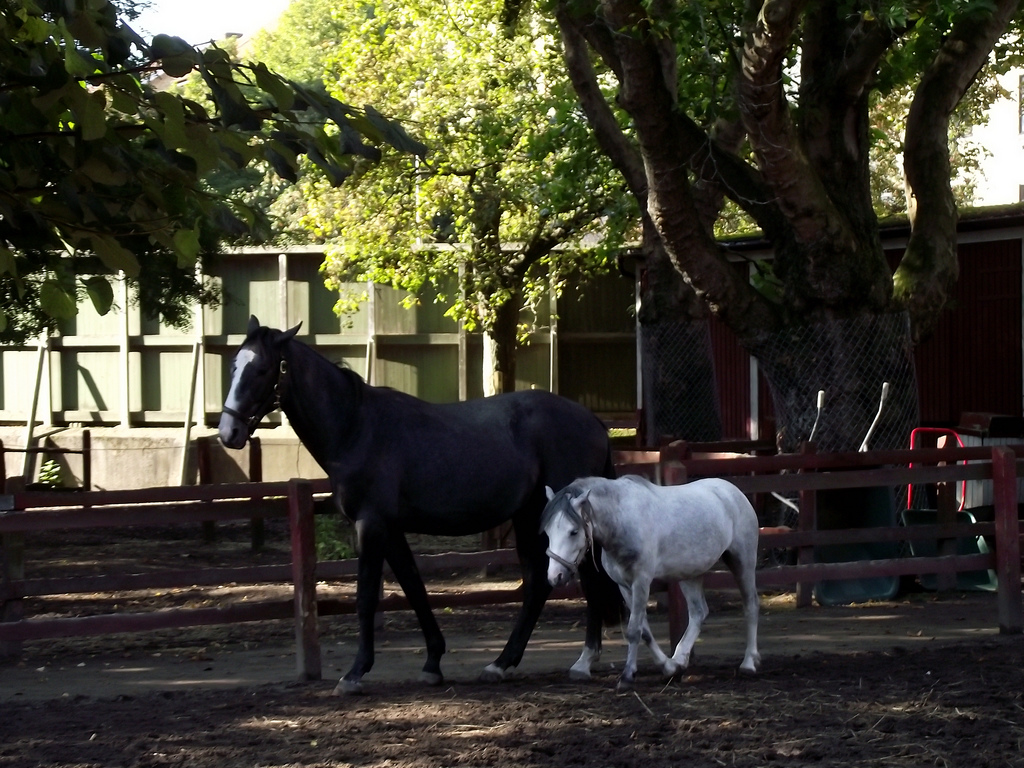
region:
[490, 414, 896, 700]
The small white horse is walking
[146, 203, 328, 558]
The brown horse has a white stripe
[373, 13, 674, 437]
The tree trunk is thin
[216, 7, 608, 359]
The tree has green leaves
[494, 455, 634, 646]
The white horse has a bridle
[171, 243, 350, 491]
The brown horse has a bride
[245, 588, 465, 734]
The brown horse has a hoof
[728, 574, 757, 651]
leg of the horse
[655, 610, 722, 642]
leg of the horse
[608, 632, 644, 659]
leg of the horse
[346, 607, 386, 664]
leg of the horse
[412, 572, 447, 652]
leg of the horse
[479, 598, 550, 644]
leg of the horse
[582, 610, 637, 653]
leg of the horse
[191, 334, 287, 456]
head of the horse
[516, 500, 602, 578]
head of the horse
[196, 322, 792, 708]
Two horses in the field.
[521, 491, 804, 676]
The pony is white.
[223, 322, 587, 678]
The horse is black.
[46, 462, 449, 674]
The fence is red and wooden.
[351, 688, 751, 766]
Dirt on the ground.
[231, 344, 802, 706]
The small horse is next to the big horse.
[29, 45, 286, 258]
The tree has big green leaves.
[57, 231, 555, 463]
A green wall behind the tree.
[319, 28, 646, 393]
The tree is green.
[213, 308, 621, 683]
A black and white horse on the pasture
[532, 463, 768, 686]
A Grey pony on the pasture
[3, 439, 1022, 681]
A fence on the pasture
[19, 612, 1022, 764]
The Pasture for the horses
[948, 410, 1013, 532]
A trashbin near the pasture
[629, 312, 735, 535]
Meshing around the tree to keep it safe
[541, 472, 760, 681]
small white and gray horse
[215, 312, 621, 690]
tall black horse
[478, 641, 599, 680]
white feet on a black horse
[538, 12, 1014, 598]
tall brown tree with thick branches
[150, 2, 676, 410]
tall tree with green leaves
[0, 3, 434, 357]
tall tree with green leaves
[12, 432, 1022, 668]
red wooden fence around field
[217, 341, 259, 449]
white stripe down face of black horse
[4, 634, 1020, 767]
brown dirt in pasture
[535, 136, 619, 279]
green leaves on the tree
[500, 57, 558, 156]
green leaves on the tree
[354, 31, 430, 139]
green leaves on the tree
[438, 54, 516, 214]
green leaves on the tree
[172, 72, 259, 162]
green leaves on the tree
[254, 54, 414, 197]
green leaves on the tree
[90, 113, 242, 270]
green leaves on the tree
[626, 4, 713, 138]
green leaves on the tree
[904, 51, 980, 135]
green leaves on the tree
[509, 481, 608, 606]
the head of a horse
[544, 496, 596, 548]
the mane of a horse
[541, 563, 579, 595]
the nose of a horse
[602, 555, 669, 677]
the front legs of a horse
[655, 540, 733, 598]
the belly of a horse